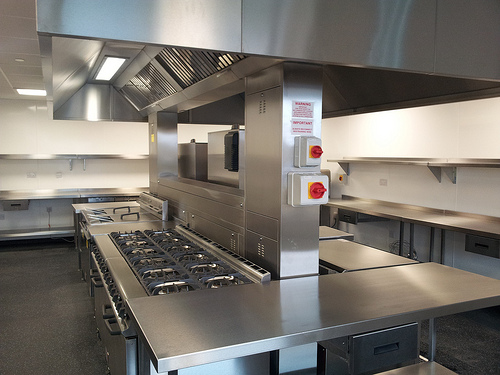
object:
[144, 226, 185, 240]
cooker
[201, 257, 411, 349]
stainless steel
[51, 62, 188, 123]
stainless steel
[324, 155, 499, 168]
shelves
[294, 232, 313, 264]
surafce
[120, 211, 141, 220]
handles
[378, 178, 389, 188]
plug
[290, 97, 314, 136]
warning label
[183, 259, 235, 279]
burners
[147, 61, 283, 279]
wall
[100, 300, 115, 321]
handle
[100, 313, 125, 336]
handle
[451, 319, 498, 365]
ground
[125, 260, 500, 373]
steel table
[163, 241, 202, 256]
stove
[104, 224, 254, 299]
stove units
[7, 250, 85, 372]
floor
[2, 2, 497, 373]
kitchen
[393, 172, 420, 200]
white wall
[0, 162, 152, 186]
wall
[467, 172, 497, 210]
white wall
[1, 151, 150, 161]
shelves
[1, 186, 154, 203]
shelves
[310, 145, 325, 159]
buttons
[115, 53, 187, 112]
vent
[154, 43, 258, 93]
vent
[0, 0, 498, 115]
ceiling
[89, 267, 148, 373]
ovens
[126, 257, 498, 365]
countertop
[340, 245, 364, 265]
countertop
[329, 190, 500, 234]
countertop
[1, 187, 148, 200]
countertop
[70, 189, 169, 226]
frying machine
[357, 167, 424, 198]
wall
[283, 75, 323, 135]
wall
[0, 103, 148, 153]
wall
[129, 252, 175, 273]
stove